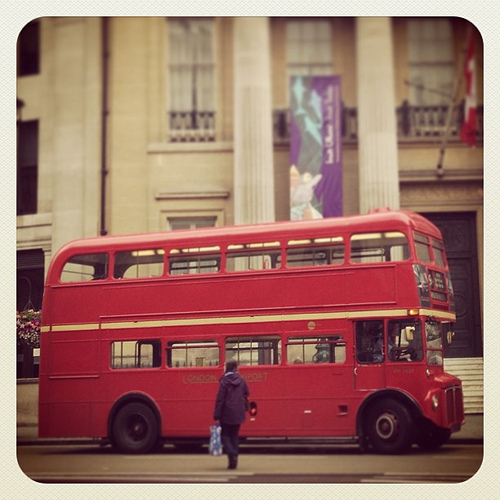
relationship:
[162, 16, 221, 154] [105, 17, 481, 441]
window on building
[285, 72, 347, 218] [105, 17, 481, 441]
flag hanging from building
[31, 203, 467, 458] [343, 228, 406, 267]
bus has window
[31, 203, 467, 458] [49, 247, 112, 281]
bus has window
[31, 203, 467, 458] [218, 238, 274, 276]
bus has window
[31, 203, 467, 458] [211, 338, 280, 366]
bus has window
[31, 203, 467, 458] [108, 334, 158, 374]
bus has window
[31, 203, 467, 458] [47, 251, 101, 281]
bus has window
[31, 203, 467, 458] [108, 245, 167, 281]
bus has window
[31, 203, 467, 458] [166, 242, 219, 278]
bus has window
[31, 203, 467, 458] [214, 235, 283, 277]
bus has window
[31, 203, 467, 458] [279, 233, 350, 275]
bus has window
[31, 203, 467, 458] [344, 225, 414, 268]
bus has window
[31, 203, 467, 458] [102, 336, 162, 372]
bus has window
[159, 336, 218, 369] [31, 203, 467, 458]
window on bus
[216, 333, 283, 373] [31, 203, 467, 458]
window on bus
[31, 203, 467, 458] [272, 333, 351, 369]
bus has window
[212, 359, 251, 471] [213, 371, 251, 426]
girl wearing coat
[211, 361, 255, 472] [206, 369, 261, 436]
girl wearing jacket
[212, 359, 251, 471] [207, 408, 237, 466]
girl holding bag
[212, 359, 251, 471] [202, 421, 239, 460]
girl holding bag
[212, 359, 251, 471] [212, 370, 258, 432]
girl wearing coat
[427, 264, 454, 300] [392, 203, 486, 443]
sign on front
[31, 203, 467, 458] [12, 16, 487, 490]
bus in foreground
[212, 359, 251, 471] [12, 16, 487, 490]
girl in foreground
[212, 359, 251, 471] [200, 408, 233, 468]
girl holding bag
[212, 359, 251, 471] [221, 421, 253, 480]
girl wearing jeans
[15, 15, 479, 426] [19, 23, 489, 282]
building in background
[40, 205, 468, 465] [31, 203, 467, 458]
view of bus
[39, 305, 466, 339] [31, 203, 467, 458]
line on bus